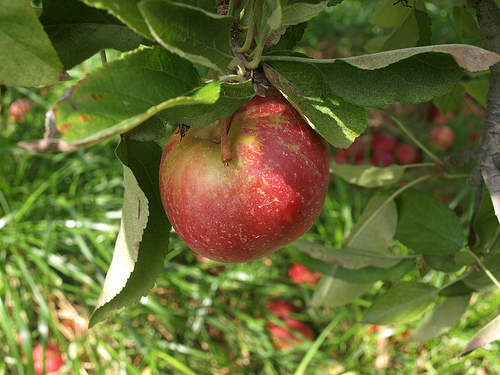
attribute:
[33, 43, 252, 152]
leaf — green, discolored, turned, shady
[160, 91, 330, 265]
apple — red, below, spotted, hanging, full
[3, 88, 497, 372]
grass — green, sunny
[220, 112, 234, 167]
stem — brown